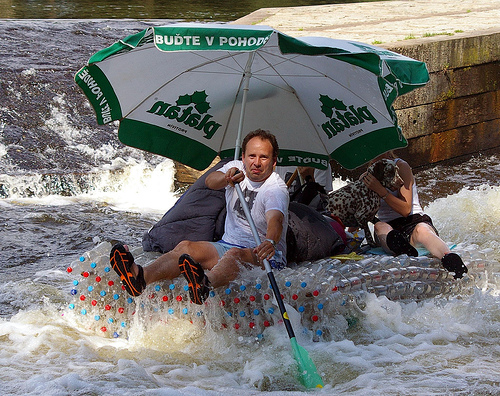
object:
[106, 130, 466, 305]
people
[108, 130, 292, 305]
man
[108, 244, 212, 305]
shoes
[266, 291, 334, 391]
paddle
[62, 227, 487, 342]
raft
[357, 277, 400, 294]
bottles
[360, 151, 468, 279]
woman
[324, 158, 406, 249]
dog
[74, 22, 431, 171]
umbrella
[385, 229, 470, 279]
black shoes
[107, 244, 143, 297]
bottom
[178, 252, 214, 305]
shoe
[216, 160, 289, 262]
white shirt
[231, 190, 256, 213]
graphics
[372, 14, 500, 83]
bricks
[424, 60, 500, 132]
moss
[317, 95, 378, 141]
letters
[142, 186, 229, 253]
sleeping bag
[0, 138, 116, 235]
water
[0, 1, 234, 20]
water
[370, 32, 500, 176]
wall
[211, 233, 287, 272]
shorts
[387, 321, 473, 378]
white caps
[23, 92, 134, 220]
waterfall